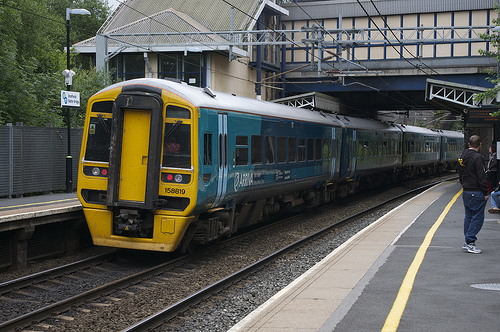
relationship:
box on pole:
[61, 68, 74, 85] [62, 18, 73, 192]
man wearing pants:
[455, 134, 490, 251] [459, 188, 487, 244]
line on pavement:
[380, 188, 461, 329] [332, 180, 499, 330]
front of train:
[74, 74, 203, 256] [68, 55, 205, 277]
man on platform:
[458, 134, 490, 253] [320, 175, 495, 330]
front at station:
[76, 76, 465, 254] [8, 91, 498, 329]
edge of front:
[181, 143, 206, 175] [76, 76, 465, 254]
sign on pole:
[48, 84, 80, 109] [59, 3, 80, 190]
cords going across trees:
[46, 0, 233, 69] [3, 2, 132, 152]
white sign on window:
[187, 74, 198, 88] [182, 54, 207, 86]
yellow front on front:
[75, 78, 192, 257] [76, 76, 465, 254]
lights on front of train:
[81, 144, 302, 212] [89, 77, 409, 244]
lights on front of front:
[85, 159, 187, 183] [76, 76, 465, 254]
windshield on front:
[87, 113, 117, 163] [76, 76, 465, 254]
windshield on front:
[164, 119, 190, 171] [76, 76, 465, 254]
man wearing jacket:
[458, 134, 490, 253] [458, 145, 490, 190]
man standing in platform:
[458, 134, 490, 253] [228, 166, 499, 330]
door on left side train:
[214, 113, 228, 208] [71, 73, 496, 275]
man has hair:
[458, 134, 490, 253] [467, 132, 487, 147]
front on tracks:
[76, 76, 465, 254] [4, 237, 277, 327]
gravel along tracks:
[133, 189, 428, 330] [1, 172, 460, 327]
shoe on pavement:
[461, 242, 482, 254] [230, 173, 499, 330]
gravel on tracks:
[242, 252, 310, 304] [46, 228, 273, 303]